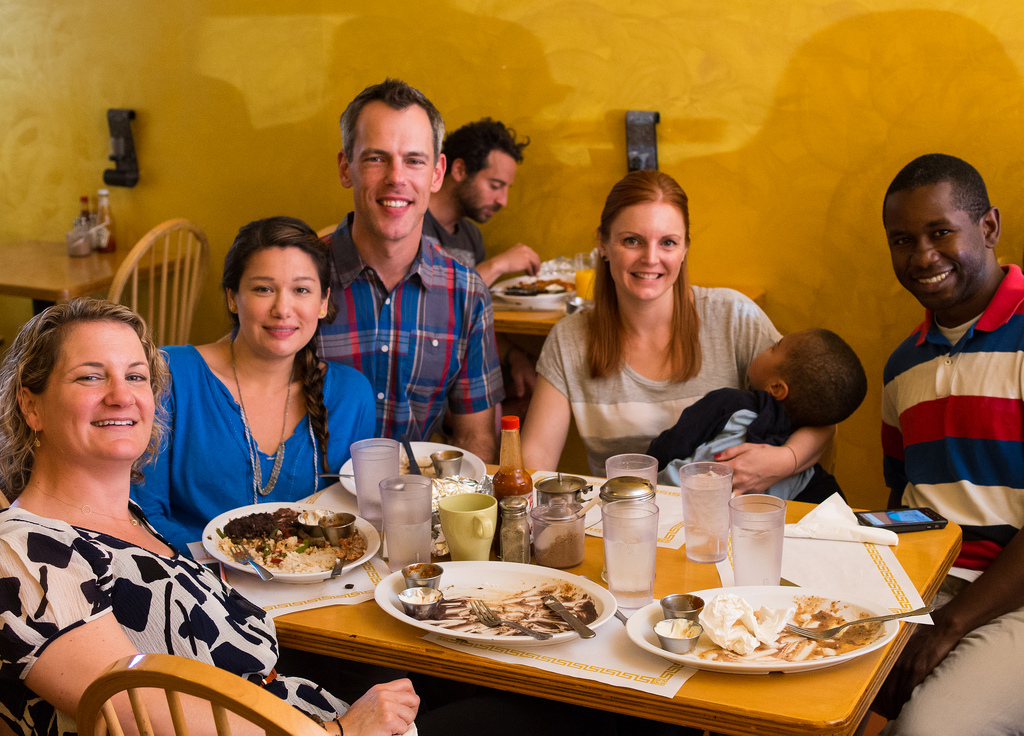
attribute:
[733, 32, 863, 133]
wall — yellow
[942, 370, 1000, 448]
shirt — blue, white, red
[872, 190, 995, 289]
guy — black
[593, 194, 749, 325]
woman — white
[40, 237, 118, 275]
table — brown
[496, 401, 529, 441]
lid — red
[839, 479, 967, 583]
phone — on